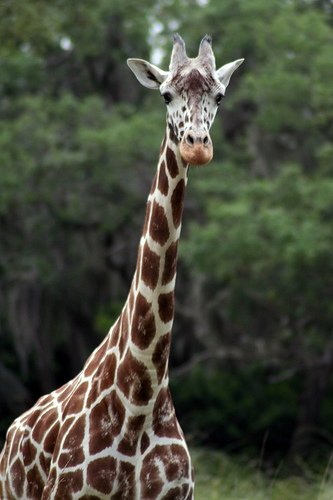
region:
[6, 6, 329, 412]
Trees are in the background.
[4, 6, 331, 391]
The trees are blurry.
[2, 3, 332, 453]
the trees are green.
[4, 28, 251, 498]
The giraffe is brown and white.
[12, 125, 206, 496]
The giraffe has spots.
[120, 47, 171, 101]
the giraffe's ear is white.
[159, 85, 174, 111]
the giraffe's eye is black.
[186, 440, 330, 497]
The grass is green.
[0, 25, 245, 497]
Only one giraffe visible.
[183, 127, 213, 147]
The giraffes nose is black.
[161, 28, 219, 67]
two giraffe ossicones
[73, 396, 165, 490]
brown and white giraffe fur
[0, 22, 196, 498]
tall giraffe standing in grass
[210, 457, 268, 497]
patch of tall green grass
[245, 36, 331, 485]
tall green trees and foliage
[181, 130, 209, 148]
two giraffe nostrils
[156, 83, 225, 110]
two giraffe eyes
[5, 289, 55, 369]
brown tree bark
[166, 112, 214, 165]
long tan giraffe snout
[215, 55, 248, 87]
one white giraffe ear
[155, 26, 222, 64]
The giraffe has two horns.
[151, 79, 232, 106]
The giraffe has two eyes.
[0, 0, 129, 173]
The green trees behind the giraffe.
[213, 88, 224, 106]
An eye on the giraffe.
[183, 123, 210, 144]
The giraffe has two nostrils.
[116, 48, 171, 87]
The giraffe has an ear.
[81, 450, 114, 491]
The spot on the giraffe.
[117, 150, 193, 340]
The giraffe has a long neck.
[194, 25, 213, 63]
A horn on the giraffe.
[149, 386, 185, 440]
A large brown spot on the giraffe.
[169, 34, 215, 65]
Top two horns on a giraffes head.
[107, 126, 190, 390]
Thin neck of a brown and white giraffe.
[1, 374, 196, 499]
Lower body of a brown and white giraffe.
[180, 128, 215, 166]
Front snout of a giraffe.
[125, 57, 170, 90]
A giraffes right side ear.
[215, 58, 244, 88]
Left side ear of a giraffe.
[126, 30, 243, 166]
Head of a brown and white giraffe.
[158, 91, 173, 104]
A giraffes right side eye.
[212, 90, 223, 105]
A giraffes left side eye.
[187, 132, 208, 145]
Two nostrils of a giraffe.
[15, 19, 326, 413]
giraffe staring at camera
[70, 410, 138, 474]
brown and white animal print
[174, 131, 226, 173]
two nostrils of giraffe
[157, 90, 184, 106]
left black eye of giraffe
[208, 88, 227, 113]
right black eye of giraffe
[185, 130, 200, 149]
left nostril of giraffe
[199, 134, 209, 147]
right nostril of giraffe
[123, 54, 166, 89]
left ear of giraffe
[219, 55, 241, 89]
right ear of giraffe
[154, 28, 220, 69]
knobby horns of giraffe